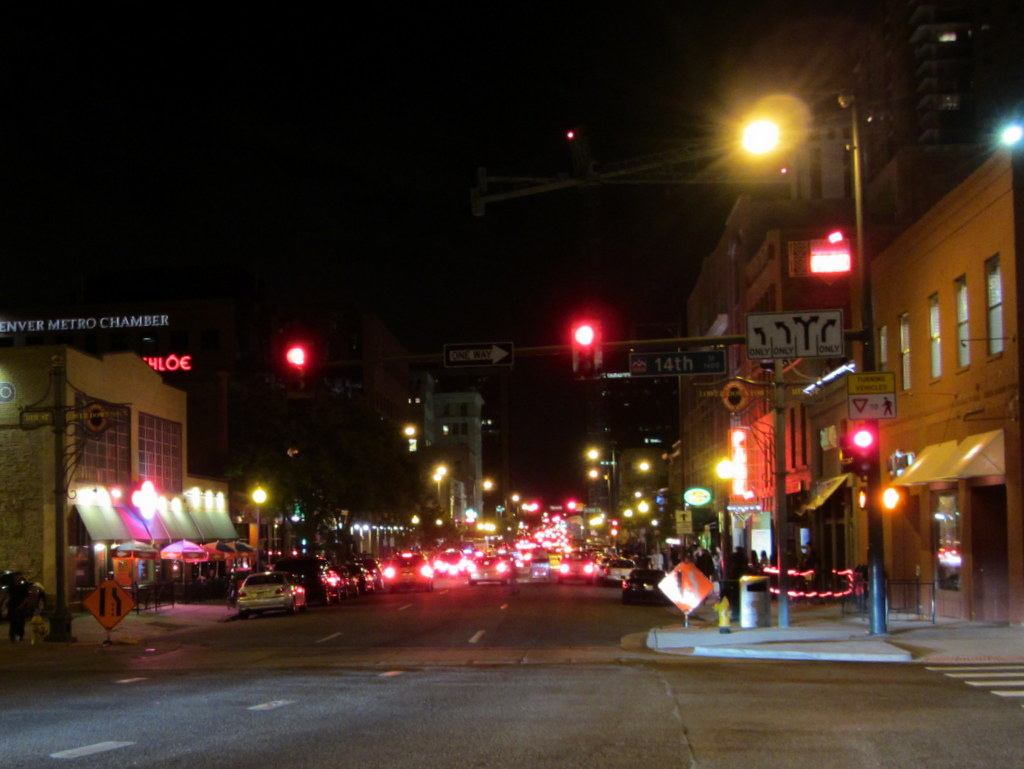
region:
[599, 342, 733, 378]
traffic sign on the pole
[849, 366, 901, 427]
traffic sign is yellow and white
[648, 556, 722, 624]
traffic sign is orange and black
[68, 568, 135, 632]
traffic sign is orange and black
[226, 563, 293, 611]
Car parked on the street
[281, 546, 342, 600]
Car parked on the street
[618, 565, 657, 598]
Car parked on the street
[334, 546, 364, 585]
Car parked on the street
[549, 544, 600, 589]
Car parked on the street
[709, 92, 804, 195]
THIS LIGHT IS YELLOW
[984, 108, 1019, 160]
THE LIGHT IS WHITE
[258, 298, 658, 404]
THE LIGHTS ARE RED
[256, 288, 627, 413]
THESE ARE TRAFFIC LIGHTS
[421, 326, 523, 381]
THE SIGN SAYS ONE WAY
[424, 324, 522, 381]
THIS IS A SIGN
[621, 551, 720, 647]
THIS SIGN IS DIAMOND SHAPED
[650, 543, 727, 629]
THIS SIGN IS ORANGE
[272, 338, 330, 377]
Red light illuminated on traffic signal.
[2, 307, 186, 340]
White letters on sign.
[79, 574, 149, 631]
Black and orange diamond shaped sign.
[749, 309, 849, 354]
White sign with black arrows.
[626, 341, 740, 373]
Green and white street sign.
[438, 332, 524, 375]
Black and white street sign.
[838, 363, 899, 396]
Yellow sign attached to pole.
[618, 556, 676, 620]
Black car on road.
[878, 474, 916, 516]
Do not walk light is illuminated.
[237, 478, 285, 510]
Yellow street light is on.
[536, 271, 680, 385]
red light on pole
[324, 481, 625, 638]
cars on the street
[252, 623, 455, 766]
white lines on ground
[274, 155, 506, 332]
sky above the street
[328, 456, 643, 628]
many lights on the street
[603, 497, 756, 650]
sign next to street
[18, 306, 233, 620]
building near the street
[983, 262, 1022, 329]
a window on the building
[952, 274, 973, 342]
a window on the building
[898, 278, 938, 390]
a window on the building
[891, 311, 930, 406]
a window on the building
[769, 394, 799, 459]
a window on the building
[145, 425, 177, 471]
a window on the building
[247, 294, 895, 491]
this is a stop light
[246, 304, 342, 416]
the light is illuminated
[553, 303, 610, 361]
this is a red light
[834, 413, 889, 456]
the red light is illuminated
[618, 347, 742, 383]
this is a street sign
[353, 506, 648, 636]
there are red taillights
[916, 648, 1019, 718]
this is a crosswalk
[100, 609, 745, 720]
a crosswalk at an intersection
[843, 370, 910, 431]
this is a pedestrian yield sign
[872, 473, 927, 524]
the Do Not walk symbol is illuminated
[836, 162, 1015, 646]
building on the side of the road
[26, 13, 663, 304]
the sky above the buildings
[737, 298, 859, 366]
a sign on the structure